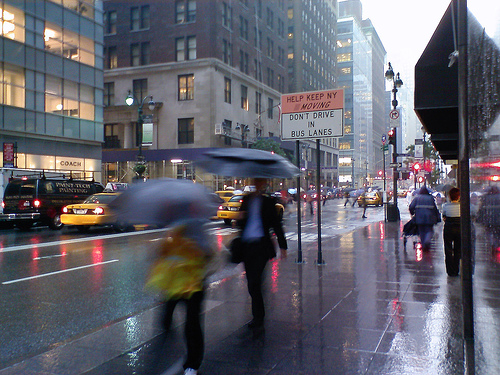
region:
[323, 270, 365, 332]
part of a floor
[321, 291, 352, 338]
part of a floor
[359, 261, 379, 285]
part of a floor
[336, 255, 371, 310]
part of a floor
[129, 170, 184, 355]
person by road with umbrella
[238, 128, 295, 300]
person by road with umbrella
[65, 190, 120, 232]
back of taxi cab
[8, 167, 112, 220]
green van on road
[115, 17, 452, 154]
tall buildings on left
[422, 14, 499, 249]
back of street sign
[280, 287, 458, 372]
wet sidewalk on right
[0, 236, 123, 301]
white lines on road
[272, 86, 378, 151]
orange and white sign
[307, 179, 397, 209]
people crossing wet street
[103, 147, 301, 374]
pedestrians walking very fast on sidewalk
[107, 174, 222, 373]
walking so fast person is captured as a blurr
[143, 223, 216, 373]
wearing a yellow raincoat under umbrella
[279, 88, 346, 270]
road sign to help keep traffic steady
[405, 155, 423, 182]
stop light displays red light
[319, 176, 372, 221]
pedestrians walking quickly across street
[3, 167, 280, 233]
slowed or stopped traffic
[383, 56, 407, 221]
tall street light on sidewalk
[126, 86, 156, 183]
street light on sidewalk one is on and one is off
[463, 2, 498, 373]
pane of glass covered in droplets of water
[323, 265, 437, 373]
the sidewalk is wet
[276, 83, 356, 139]
the sign is rectangular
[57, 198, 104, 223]
the cars brake lights are on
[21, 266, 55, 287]
the line is white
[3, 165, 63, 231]
the van is black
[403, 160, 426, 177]
the light is red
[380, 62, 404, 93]
the street lights are off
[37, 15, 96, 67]
the building has wide windows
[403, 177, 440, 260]
the person is walking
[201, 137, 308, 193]
the umbrella is open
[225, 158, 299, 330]
this is a man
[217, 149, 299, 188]
this is a umbrella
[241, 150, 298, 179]
the umbrella is black in color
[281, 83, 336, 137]
this is a signpost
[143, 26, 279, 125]
this is a building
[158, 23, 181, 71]
this is the wall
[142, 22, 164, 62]
the wall is brown in color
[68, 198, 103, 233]
this is a car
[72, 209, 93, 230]
the car is yellow in color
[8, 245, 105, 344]
this is the road